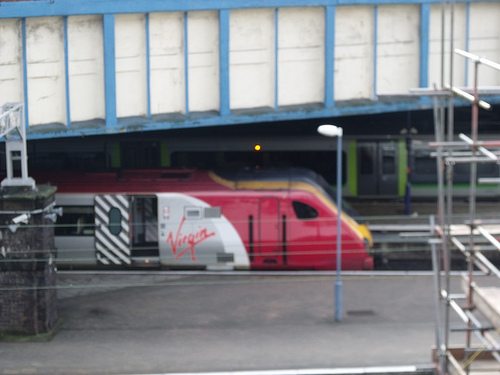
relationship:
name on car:
[165, 218, 217, 261] [0, 165, 372, 269]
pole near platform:
[311, 120, 369, 325] [55, 239, 458, 371]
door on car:
[93, 192, 133, 269] [9, 191, 251, 268]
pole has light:
[333, 126, 343, 322] [317, 119, 344, 136]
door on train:
[378, 142, 400, 195] [37, 141, 498, 202]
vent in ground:
[344, 309, 376, 316] [104, 275, 462, 371]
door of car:
[93, 187, 132, 273] [55, 191, 251, 273]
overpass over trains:
[1, 2, 498, 148] [40, 128, 498, 273]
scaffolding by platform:
[413, 44, 499, 371] [10, 265, 499, 362]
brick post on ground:
[0, 186, 55, 342] [0, 275, 461, 372]